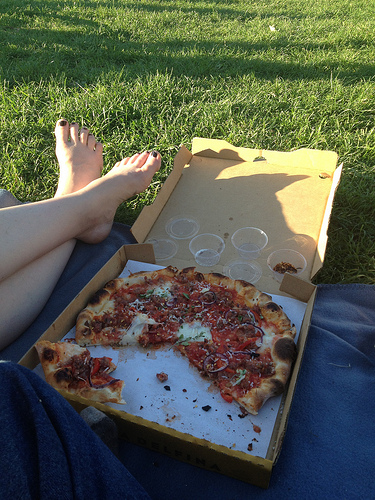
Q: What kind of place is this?
A: It is a field.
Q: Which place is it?
A: It is a field.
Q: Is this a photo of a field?
A: Yes, it is showing a field.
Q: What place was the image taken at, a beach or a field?
A: It was taken at a field.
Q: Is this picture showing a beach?
A: No, the picture is showing a field.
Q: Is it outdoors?
A: Yes, it is outdoors.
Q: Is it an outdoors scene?
A: Yes, it is outdoors.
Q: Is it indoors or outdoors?
A: It is outdoors.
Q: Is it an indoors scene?
A: No, it is outdoors.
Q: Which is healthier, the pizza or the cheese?
A: The cheese is healthier than the pizza.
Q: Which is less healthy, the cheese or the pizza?
A: The pizza is less healthy than the cheese.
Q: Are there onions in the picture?
A: Yes, there are onions.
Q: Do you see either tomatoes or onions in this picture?
A: Yes, there are onions.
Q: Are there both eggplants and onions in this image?
A: No, there are onions but no eggplants.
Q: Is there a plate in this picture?
A: No, there are no plates.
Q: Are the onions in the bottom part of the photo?
A: Yes, the onions are in the bottom of the image.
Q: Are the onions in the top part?
A: No, the onions are in the bottom of the image.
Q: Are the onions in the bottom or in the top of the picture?
A: The onions are in the bottom of the image.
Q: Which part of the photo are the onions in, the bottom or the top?
A: The onions are in the bottom of the image.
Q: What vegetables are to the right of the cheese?
A: The vegetables are onions.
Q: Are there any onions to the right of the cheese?
A: Yes, there are onions to the right of the cheese.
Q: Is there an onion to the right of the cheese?
A: Yes, there are onions to the right of the cheese.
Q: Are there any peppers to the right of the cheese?
A: No, there are onions to the right of the cheese.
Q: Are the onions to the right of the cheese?
A: Yes, the onions are to the right of the cheese.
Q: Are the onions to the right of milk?
A: No, the onions are to the right of the cheese.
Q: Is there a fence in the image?
A: No, there are no fences.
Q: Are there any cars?
A: No, there are no cars.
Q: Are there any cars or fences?
A: No, there are no cars or fences.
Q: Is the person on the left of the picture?
A: Yes, the person is on the left of the image.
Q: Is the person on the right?
A: No, the person is on the left of the image.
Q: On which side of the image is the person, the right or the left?
A: The person is on the left of the image.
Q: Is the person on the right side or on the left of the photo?
A: The person is on the left of the image.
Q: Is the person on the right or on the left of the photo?
A: The person is on the left of the image.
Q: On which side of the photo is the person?
A: The person is on the left of the image.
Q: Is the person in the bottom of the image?
A: Yes, the person is in the bottom of the image.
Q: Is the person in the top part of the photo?
A: No, the person is in the bottom of the image.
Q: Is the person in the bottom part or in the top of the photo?
A: The person is in the bottom of the image.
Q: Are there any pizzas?
A: Yes, there is a pizza.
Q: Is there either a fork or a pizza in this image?
A: Yes, there is a pizza.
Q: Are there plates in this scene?
A: No, there are no plates.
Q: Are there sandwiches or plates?
A: No, there are no plates or sandwiches.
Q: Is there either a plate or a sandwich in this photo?
A: No, there are no plates or sandwiches.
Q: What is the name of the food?
A: The food is a pizza.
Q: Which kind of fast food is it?
A: The food is a pizza.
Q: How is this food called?
A: This is a pizza.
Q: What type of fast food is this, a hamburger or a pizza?
A: This is a pizza.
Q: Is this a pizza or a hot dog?
A: This is a pizza.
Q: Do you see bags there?
A: No, there are no bags.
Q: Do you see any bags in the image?
A: No, there are no bags.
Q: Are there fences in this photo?
A: No, there are no fences.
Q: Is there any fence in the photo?
A: No, there are no fences.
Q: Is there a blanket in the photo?
A: Yes, there is a blanket.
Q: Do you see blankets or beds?
A: Yes, there is a blanket.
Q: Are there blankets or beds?
A: Yes, there is a blanket.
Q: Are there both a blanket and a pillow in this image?
A: No, there is a blanket but no pillows.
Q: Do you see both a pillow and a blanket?
A: No, there is a blanket but no pillows.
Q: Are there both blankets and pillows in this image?
A: No, there is a blanket but no pillows.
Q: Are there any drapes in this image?
A: No, there are no drapes.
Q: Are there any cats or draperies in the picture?
A: No, there are no draperies or cats.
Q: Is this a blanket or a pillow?
A: This is a blanket.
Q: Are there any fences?
A: No, there are no fences.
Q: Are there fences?
A: No, there are no fences.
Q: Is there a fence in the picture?
A: No, there are no fences.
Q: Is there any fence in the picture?
A: No, there are no fences.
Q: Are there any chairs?
A: No, there are no chairs.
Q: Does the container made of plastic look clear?
A: Yes, the container is clear.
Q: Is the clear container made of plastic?
A: Yes, the container is made of plastic.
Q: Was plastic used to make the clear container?
A: Yes, the container is made of plastic.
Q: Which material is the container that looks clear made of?
A: The container is made of plastic.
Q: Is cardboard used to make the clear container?
A: No, the container is made of plastic.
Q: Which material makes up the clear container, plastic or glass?
A: The container is made of plastic.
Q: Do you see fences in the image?
A: No, there are no fences.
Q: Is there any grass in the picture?
A: Yes, there is grass.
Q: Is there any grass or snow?
A: Yes, there is grass.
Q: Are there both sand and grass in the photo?
A: No, there is grass but no sand.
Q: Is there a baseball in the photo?
A: No, there are no baseballs.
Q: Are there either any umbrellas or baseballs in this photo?
A: No, there are no baseballs or umbrellas.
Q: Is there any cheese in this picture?
A: Yes, there is cheese.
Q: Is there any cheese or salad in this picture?
A: Yes, there is cheese.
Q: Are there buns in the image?
A: No, there are no buns.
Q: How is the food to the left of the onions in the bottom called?
A: The food is cheese.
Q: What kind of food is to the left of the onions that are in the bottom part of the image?
A: The food is cheese.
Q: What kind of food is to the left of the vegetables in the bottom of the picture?
A: The food is cheese.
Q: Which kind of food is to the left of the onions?
A: The food is cheese.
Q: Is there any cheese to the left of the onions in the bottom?
A: Yes, there is cheese to the left of the onions.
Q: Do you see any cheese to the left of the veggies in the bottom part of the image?
A: Yes, there is cheese to the left of the onions.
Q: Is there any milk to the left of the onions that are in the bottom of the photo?
A: No, there is cheese to the left of the onions.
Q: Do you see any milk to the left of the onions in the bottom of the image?
A: No, there is cheese to the left of the onions.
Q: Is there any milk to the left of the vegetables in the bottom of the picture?
A: No, there is cheese to the left of the onions.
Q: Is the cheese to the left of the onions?
A: Yes, the cheese is to the left of the onions.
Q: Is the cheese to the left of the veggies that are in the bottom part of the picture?
A: Yes, the cheese is to the left of the onions.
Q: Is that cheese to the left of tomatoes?
A: No, the cheese is to the left of the onions.